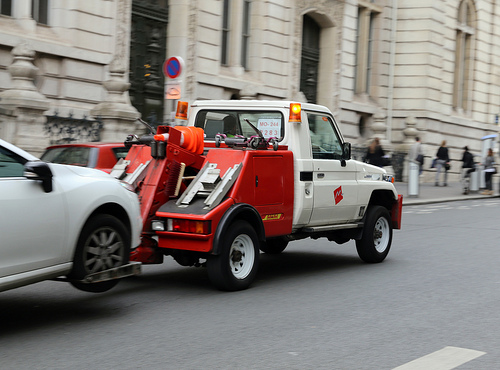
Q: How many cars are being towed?
A: One.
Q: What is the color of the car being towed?
A: White.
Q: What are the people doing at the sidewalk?
A: Walking.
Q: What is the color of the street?
A: Gray.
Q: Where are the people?
A: At the sidewalk.